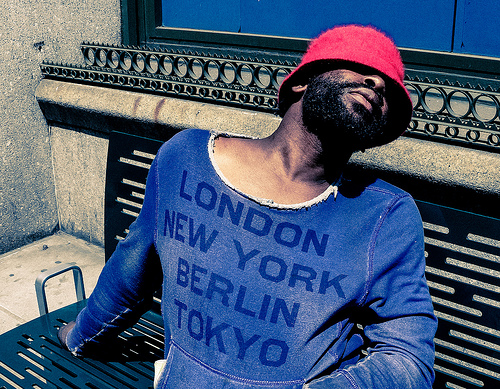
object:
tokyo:
[172, 298, 288, 368]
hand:
[58, 321, 75, 346]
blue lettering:
[161, 166, 348, 368]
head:
[289, 67, 391, 156]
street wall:
[34, 77, 268, 139]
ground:
[418, 217, 450, 252]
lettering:
[300, 228, 330, 256]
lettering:
[241, 205, 273, 238]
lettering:
[193, 179, 217, 210]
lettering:
[318, 268, 346, 298]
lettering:
[258, 337, 290, 367]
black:
[436, 206, 480, 230]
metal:
[430, 245, 441, 268]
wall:
[0, 0, 499, 255]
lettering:
[161, 208, 176, 241]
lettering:
[299, 226, 334, 256]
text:
[157, 167, 351, 366]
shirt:
[63, 124, 437, 388]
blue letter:
[286, 260, 318, 293]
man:
[55, 22, 438, 387]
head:
[287, 29, 396, 151]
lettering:
[230, 325, 261, 363]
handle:
[35, 261, 85, 325]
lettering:
[284, 261, 317, 293]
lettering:
[202, 315, 228, 356]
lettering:
[231, 283, 257, 316]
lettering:
[188, 219, 219, 252]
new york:
[163, 205, 349, 298]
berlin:
[161, 257, 307, 330]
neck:
[260, 115, 368, 181]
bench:
[0, 128, 497, 385]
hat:
[275, 24, 412, 146]